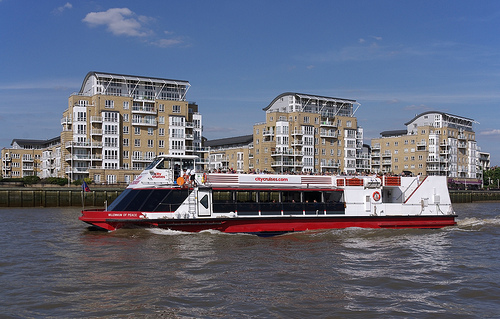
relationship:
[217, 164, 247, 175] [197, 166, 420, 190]
people are on upper deck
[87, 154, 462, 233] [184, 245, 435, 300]
boat in water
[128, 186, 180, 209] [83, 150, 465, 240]
window on boat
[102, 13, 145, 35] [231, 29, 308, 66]
cloud in sky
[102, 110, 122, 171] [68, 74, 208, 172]
windows are on building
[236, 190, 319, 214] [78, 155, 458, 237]
windows are on boat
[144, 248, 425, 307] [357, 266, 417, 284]
water has small waves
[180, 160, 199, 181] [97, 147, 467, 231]
people are on cruise ship